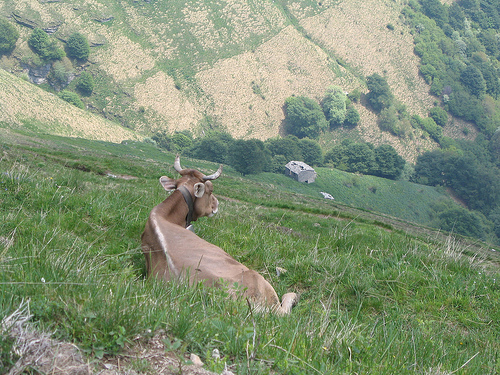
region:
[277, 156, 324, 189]
barn on side of hill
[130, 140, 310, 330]
bull laying on grass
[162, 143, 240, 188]
horns on a bull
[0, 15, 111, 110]
trees on the side of a hill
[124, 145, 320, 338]
bull laying on grass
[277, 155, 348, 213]
building on a hill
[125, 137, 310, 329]
brown cow in a field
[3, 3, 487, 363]
hillside with cow and barn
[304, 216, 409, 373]
part of a hillside with green grass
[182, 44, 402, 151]
brown field at bottom of hill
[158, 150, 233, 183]
horns on cow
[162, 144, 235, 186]
white horns on a cow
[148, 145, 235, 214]
horns on head of cow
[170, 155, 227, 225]
brown head of cow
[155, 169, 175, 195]
white and brown ear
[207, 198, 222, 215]
small white snout of cow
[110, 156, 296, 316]
brown cow laying down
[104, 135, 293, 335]
cow laying in field of grass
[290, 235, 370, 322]
green and brown grass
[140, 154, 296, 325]
brown cow in grass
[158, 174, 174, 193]
grey ear on cow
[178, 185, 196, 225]
brown collar on cow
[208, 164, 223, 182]
grey horn on cow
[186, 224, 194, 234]
metal bell on cow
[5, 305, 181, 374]
dead grass on field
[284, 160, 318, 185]
grey barn on field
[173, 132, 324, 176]
trees with green leaves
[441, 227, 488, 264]
brown weeds in grass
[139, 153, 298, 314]
cow laying in field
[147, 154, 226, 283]
A goat lying on the grass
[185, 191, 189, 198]
A collar on the neck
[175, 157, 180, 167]
Horn standing up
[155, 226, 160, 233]
Spine on the back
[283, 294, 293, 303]
Leg on the grass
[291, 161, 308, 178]
A building on a slope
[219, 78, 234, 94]
Bare surface on the hill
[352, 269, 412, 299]
Grass on the ground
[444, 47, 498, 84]
Forest on the hillside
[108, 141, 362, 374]
a cow laying down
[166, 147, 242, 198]
horns on the head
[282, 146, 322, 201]
a barn in the distance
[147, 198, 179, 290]
white stripe on back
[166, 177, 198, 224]
a black collar on neck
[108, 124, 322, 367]
a large brown cow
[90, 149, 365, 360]
a cow laying down resting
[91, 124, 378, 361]
a cow on a hill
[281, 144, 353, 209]
a gray building below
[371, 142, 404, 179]
A tree in a field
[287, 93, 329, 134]
A tree in a field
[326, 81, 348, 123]
A tree in a field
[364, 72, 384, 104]
A tree in a field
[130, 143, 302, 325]
brown and white cow laying in the grass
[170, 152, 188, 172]
left horn on the cow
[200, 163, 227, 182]
right horn on the cow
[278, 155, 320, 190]
house in the field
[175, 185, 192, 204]
black collar around the neck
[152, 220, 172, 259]
white fur on the cow's back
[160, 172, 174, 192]
left ear on the cow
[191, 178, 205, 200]
right ear on the cow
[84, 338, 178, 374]
dirt patch on the grass